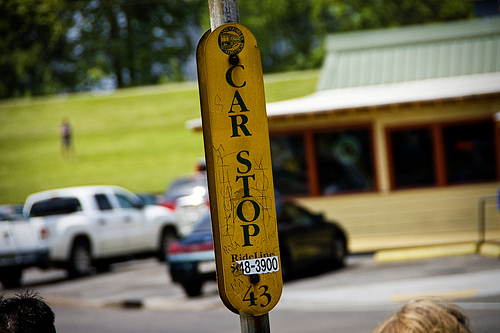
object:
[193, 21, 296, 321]
sign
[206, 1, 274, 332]
pole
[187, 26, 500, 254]
restaurant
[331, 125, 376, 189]
customers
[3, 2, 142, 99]
trees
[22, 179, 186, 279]
cars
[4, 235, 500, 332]
parking lot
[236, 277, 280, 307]
number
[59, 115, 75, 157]
person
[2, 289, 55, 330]
hair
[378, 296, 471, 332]
hair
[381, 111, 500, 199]
windows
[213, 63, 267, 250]
car stop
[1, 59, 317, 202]
grass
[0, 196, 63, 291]
truck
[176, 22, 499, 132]
roof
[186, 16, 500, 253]
building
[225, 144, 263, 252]
stop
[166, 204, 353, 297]
car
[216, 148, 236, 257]
graffiti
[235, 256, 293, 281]
sticker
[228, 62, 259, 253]
writing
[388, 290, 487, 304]
line